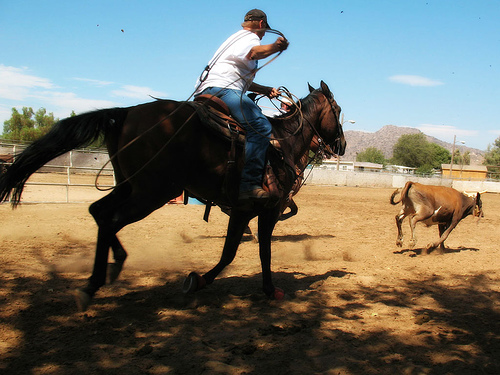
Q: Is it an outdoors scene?
A: Yes, it is outdoors.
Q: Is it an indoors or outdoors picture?
A: It is outdoors.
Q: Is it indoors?
A: No, it is outdoors.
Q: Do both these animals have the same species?
A: No, they are horses and cows.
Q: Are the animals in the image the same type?
A: No, they are horses and cows.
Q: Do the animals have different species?
A: Yes, they are horses and cows.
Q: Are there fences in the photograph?
A: Yes, there is a fence.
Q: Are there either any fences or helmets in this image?
A: Yes, there is a fence.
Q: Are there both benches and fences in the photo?
A: No, there is a fence but no benches.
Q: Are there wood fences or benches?
A: Yes, there is a wood fence.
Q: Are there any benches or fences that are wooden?
A: Yes, the fence is wooden.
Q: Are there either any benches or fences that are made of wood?
A: Yes, the fence is made of wood.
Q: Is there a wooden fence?
A: Yes, there is a wood fence.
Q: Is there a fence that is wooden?
A: Yes, there is a fence that is wooden.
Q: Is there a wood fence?
A: Yes, there is a fence that is made of wood.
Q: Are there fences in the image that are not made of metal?
A: Yes, there is a fence that is made of wood.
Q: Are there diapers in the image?
A: No, there are no diapers.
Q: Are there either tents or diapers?
A: No, there are no diapers or tents.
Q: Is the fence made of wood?
A: Yes, the fence is made of wood.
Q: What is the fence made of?
A: The fence is made of wood.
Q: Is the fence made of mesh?
A: No, the fence is made of wood.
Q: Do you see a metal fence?
A: No, there is a fence but it is made of wood.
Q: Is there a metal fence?
A: No, there is a fence but it is made of wood.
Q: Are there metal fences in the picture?
A: No, there is a fence but it is made of wood.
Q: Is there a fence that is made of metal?
A: No, there is a fence but it is made of wood.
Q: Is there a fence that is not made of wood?
A: No, there is a fence but it is made of wood.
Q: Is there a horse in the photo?
A: Yes, there is a horse.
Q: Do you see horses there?
A: Yes, there is a horse.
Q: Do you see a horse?
A: Yes, there is a horse.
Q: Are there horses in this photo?
A: Yes, there is a horse.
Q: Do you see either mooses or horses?
A: Yes, there is a horse.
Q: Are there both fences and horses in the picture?
A: Yes, there are both a horse and a fence.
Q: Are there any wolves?
A: No, there are no wolves.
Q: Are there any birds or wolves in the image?
A: No, there are no wolves or birds.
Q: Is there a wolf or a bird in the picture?
A: No, there are no wolves or birds.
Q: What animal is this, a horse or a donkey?
A: This is a horse.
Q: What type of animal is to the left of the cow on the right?
A: The animal is a horse.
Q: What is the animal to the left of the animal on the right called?
A: The animal is a horse.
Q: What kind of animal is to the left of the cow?
A: The animal is a horse.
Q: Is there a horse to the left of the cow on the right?
A: Yes, there is a horse to the left of the cow.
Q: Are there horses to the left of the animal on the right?
A: Yes, there is a horse to the left of the cow.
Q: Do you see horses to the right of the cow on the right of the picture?
A: No, the horse is to the left of the cow.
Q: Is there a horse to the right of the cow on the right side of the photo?
A: No, the horse is to the left of the cow.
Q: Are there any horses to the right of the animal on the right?
A: No, the horse is to the left of the cow.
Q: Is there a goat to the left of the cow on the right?
A: No, there is a horse to the left of the cow.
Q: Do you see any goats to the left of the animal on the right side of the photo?
A: No, there is a horse to the left of the cow.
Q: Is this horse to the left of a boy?
A: No, the horse is to the left of the cow.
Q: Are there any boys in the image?
A: No, there are no boys.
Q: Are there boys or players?
A: No, there are no boys or players.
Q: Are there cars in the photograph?
A: No, there are no cars.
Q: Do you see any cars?
A: No, there are no cars.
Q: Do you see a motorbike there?
A: No, there are no motorcycles.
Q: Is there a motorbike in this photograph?
A: No, there are no motorcycles.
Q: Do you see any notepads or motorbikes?
A: No, there are no motorbikes or notepads.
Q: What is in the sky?
A: The clouds are in the sky.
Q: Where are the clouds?
A: The clouds are in the sky.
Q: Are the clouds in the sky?
A: Yes, the clouds are in the sky.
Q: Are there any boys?
A: No, there are no boys.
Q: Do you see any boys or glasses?
A: No, there are no boys or glasses.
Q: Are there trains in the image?
A: No, there are no trains.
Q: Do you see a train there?
A: No, there are no trains.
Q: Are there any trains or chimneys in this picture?
A: No, there are no trains or chimneys.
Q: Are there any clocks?
A: No, there are no clocks.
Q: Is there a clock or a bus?
A: No, there are no clocks or buses.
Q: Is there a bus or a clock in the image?
A: No, there are no clocks or buses.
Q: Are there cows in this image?
A: Yes, there is a cow.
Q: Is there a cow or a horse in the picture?
A: Yes, there is a cow.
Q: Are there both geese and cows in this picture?
A: No, there is a cow but no geese.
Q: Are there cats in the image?
A: No, there are no cats.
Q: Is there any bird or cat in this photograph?
A: No, there are no cats or birds.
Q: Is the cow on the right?
A: Yes, the cow is on the right of the image.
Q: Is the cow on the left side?
A: No, the cow is on the right of the image.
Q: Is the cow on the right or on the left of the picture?
A: The cow is on the right of the image.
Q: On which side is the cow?
A: The cow is on the right of the image.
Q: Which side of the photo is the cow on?
A: The cow is on the right of the image.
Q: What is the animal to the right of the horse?
A: The animal is a cow.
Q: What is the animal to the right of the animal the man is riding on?
A: The animal is a cow.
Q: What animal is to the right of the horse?
A: The animal is a cow.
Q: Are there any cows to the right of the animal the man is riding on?
A: Yes, there is a cow to the right of the horse.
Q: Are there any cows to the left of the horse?
A: No, the cow is to the right of the horse.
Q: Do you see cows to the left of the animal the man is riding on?
A: No, the cow is to the right of the horse.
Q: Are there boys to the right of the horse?
A: No, there is a cow to the right of the horse.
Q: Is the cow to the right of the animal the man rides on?
A: Yes, the cow is to the right of the horse.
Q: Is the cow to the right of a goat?
A: No, the cow is to the right of the horse.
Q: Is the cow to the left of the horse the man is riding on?
A: No, the cow is to the right of the horse.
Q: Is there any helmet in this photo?
A: No, there are no helmets.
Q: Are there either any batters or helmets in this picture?
A: No, there are no helmets or batters.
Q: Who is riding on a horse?
A: The man is riding on a horse.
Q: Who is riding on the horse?
A: The man is riding on a horse.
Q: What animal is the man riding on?
A: The man is riding on a horse.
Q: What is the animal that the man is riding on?
A: The animal is a horse.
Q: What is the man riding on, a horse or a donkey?
A: The man is riding on a horse.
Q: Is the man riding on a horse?
A: Yes, the man is riding on a horse.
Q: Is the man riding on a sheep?
A: No, the man is riding on a horse.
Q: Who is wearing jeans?
A: The man is wearing jeans.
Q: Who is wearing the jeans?
A: The man is wearing jeans.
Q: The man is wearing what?
A: The man is wearing jeans.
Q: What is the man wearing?
A: The man is wearing jeans.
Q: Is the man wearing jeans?
A: Yes, the man is wearing jeans.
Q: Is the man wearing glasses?
A: No, the man is wearing jeans.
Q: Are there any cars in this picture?
A: No, there are no cars.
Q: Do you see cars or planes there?
A: No, there are no cars or planes.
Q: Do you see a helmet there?
A: No, there are no helmets.